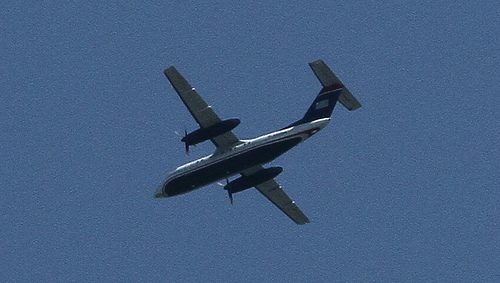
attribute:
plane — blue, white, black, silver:
[150, 58, 363, 226]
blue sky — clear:
[2, 2, 499, 280]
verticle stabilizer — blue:
[304, 60, 362, 122]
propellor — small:
[173, 127, 199, 154]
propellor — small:
[216, 174, 236, 206]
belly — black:
[165, 135, 307, 196]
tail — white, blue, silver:
[291, 57, 370, 150]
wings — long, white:
[159, 63, 308, 231]